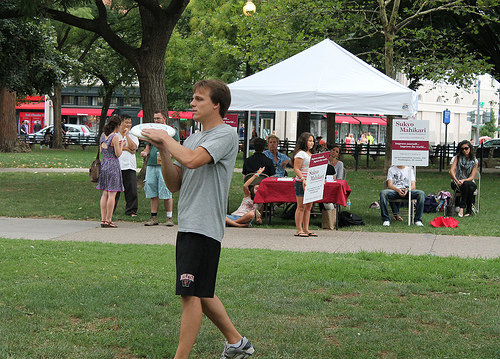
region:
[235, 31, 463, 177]
white tent set up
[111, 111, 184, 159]
man is holding a frisbee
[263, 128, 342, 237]
girl is holding a sign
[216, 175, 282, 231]
girl sitting on ground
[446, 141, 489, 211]
woman sitting in metal foldable chair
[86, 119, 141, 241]
woman is standing on sidewalk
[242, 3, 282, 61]
street light in the trees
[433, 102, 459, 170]
blue street sign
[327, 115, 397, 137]
red canopies on business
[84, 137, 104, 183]
woman is carrying a purse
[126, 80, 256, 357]
A man caught the freebie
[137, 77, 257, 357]
A man with gray shirt and white pants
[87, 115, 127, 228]
A woman with brown purse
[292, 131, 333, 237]
A woman holding a red and white sign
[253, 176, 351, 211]
A red table cloth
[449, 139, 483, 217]
A woman with sunglasses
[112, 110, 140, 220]
A man with white shirt and black pants.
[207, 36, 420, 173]
A white tent with four brown poles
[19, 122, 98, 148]
A gray and red car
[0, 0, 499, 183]
A bunch of green oak trees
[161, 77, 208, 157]
a man playing frisbee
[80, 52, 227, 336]
a man playing frisbee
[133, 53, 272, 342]
a man playing frisbee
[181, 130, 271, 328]
a man playing frisbee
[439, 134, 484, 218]
the woman is sitting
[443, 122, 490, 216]
the woman is wearing sunglasses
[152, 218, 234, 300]
the shorts are black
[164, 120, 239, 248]
the shirt is gray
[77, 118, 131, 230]
the woman is wearing a dress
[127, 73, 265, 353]
the man is holding a frisbee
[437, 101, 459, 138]
the sign is blue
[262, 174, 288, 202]
the table cloth is red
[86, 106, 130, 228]
the woman is carrying a purse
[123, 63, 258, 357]
the man is wearing shorts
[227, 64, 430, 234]
Local political campaign park.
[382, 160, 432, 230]
Person sitting behind staked sign.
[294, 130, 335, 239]
Advocate carries sign sidewalk.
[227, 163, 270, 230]
Girl blue wristband hand air.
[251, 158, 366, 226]
Red tablecloth information table.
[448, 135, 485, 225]
Woman sunglasses relaxing chair.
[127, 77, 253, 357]
Always Frisbee park game.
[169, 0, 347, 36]
Golden sun setting sky.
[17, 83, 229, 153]
Street lined red awning shops.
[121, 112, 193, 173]
Cradling white Frisbee hands.